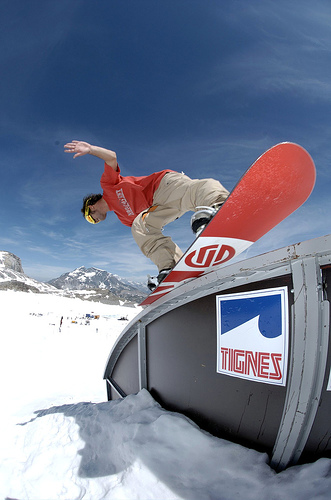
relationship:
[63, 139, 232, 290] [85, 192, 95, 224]
snowboarder wearing goggles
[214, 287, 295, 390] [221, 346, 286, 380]
sign has word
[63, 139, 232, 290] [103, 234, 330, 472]
snowboarder jumping ramp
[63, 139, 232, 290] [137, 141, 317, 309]
snowboarder riding snowboard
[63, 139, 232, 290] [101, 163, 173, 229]
snowboarder wearing tshirt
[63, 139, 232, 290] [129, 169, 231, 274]
snowboarder wearing pants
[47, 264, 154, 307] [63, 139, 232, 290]
mountain behind snowboarder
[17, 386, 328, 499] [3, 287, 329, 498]
shadow on snow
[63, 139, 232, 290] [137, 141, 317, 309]
snowboarder on snowboard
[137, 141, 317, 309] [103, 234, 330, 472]
snowboard on ramp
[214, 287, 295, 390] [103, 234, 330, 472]
sign on ramp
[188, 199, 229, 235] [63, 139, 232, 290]
snowboot on snowboarder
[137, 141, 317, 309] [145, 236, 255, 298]
snowboard has design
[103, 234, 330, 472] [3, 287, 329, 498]
ramp in snow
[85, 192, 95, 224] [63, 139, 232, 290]
goggles on snowboarder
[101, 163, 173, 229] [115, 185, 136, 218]
tshirt has writing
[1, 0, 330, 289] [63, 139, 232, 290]
sky above snowboarder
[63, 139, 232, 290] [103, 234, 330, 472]
snowboarder on ramp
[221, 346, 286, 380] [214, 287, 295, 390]
word on sign